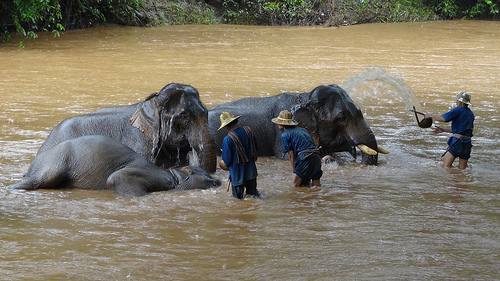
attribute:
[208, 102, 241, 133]
hat — tan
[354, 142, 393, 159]
tusks — white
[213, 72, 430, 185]
elephant — on the right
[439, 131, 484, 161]
shorts — blue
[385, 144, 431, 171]
waves — small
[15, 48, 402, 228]
elephant — wet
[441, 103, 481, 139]
shirt — blue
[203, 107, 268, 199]
man — on the right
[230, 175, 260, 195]
pants — black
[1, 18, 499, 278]
river — muddy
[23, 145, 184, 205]
elephant — on the left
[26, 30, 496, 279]
water — muddy, brown, shallow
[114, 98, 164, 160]
ear — black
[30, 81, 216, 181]
elephant — in the middle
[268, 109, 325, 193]
man — in the middle